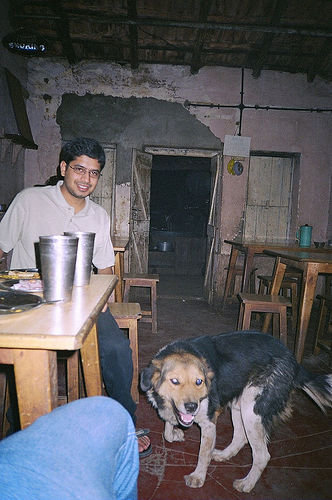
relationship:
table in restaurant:
[273, 249, 319, 290] [88, 132, 321, 334]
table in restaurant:
[225, 231, 273, 283] [88, 132, 321, 334]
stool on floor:
[237, 292, 293, 346] [158, 298, 198, 320]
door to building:
[128, 147, 151, 304] [0, 0, 331, 305]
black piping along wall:
[187, 68, 331, 134] [25, 59, 329, 307]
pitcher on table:
[292, 220, 311, 247] [258, 247, 331, 363]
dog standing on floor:
[126, 289, 305, 469] [128, 277, 330, 498]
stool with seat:
[237, 280, 285, 338] [237, 290, 294, 307]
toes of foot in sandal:
[137, 433, 152, 455] [133, 423, 156, 459]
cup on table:
[37, 235, 79, 303] [37, 308, 76, 342]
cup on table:
[62, 230, 95, 287] [37, 308, 76, 342]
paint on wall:
[49, 79, 241, 150] [6, 44, 329, 317]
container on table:
[296, 220, 312, 248] [234, 238, 249, 259]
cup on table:
[38, 235, 79, 303] [1, 265, 116, 431]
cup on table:
[63, 230, 96, 286] [1, 265, 116, 431]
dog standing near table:
[140, 329, 332, 493] [4, 278, 127, 416]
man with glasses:
[42, 144, 110, 279] [65, 161, 103, 179]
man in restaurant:
[0, 136, 153, 460] [43, 159, 307, 431]